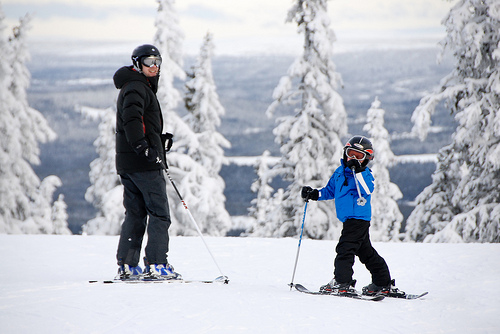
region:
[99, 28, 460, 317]
a father and son skiing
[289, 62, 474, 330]
a little boy wearing a blue parka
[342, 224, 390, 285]
black pants covering legs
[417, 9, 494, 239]
tree laden with snow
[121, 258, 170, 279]
blue snow boots on a man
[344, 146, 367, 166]
orange ski googles on a face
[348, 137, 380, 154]
a black and red helmet on a head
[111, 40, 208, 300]
a man wearing a black ski jacket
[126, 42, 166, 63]
a black helmet on a head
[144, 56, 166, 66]
black skit google on a face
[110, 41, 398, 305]
a man and a child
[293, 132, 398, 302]
a small child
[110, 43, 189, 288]
a man wearing a black coat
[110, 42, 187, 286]
a man wearing a black helmet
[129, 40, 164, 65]
a black helmet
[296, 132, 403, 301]
a small child wearing a blue coat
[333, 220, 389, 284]
black pants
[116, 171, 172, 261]
grey pants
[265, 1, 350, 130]
snow covering a tree can be seen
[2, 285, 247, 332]
white snow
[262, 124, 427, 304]
A little boy is skiing.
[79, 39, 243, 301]
A man is skiing.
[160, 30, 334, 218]
The trees are snow covered.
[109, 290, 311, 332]
The ground is snow covered.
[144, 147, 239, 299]
The man has a black and white ski pole.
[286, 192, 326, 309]
The boy has a blue and white ski pole.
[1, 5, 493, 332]
Picture was taken on a ski slope.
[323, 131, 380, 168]
The boy is wearing a helmet.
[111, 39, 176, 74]
The man is wearing a helmet.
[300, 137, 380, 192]
Boy has his hand in his mouth.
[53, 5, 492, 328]
two people skiing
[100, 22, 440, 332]
people participating in winter sports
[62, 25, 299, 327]
a man in black clothing with skis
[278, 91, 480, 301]
a kid in blue coat and orange goggles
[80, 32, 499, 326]
trees covered in snow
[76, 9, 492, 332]
two people preparing to ski down the slope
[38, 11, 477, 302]
Siblings skiing together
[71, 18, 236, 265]
man in a helmet and goggles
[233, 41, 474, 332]
a kid with one hand over his face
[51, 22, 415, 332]
they are about to ski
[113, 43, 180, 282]
a snow skier is wearing black ski jacket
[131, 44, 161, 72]
the skier is wearing a ski helmet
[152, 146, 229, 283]
the ski poles are used for balance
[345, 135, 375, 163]
the child skier is wearing a black and red helmet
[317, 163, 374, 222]
the child has a blue ski jacket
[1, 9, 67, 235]
the pine trees are covered in snow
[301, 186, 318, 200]
the child skier has black gloves on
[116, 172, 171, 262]
the man is wearing grey ski pants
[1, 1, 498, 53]
the sky is grey and cloudy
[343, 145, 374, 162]
the child skier has amber color goggle lenses